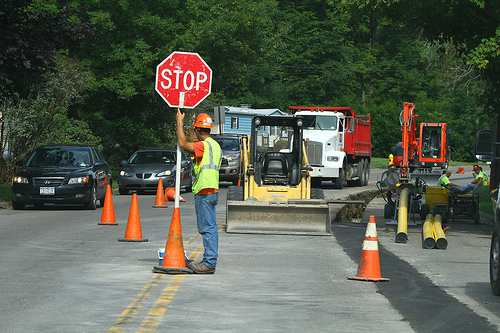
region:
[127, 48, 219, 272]
man holding stop sign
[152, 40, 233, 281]
man holding stop sign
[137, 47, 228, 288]
man holding stop sign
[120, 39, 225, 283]
man holding stop sign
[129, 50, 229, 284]
man holding stop sign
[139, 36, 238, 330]
man holding stop sign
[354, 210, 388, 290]
orange cone in street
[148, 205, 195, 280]
orange cone in street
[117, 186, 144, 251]
orange cone in street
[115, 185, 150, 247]
orange cone in street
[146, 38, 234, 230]
this is an octagon sign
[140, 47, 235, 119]
white writing on the sign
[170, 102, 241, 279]
this is a man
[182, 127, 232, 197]
man wearing a green vest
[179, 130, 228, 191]
man wearing a orange shirt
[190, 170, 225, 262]
man wearing blue jeans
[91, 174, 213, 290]
set of orange cones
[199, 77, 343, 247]
this is a bulldozer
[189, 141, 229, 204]
man wearing a safety vest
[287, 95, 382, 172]
Red and white dump truck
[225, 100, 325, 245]
bulldozer at the work site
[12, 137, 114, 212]
black car on the road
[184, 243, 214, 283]
man wearing brown work boots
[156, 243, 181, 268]
blue water cooler on the ground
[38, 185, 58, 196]
license plate on a car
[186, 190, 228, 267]
man wearing blue jeans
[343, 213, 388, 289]
safety cone on the street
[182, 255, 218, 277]
Man wearing shoes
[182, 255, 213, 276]
Man is wearing brown shoes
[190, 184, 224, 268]
Man is wearing pants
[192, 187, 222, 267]
Man wearing blue pants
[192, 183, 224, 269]
Man is wearing blue pants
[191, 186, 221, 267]
Man wearing blue jeans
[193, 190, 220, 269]
Man is wearing blue jeans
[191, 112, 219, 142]
The man is wearing a helmet.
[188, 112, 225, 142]
The mans safety helmet is orange.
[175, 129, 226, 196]
The mans safety vest is green.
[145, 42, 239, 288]
The man is directing traffic.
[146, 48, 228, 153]
The man is holding a stop sign.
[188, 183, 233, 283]
The man is wearing jeans.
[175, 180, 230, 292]
The mans pants are blue.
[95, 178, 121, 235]
The traffic cone is orange.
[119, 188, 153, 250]
The traffic cone is orange.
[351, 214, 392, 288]
a tall orange and white cone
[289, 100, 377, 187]
a red and white truck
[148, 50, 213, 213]
a red and white stop sign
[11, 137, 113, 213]
the front of a black car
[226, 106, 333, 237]
a small yellow bulldozer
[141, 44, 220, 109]
red and white stop sign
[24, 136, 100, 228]
black car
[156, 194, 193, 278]
orange colored safety cone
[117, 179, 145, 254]
orange colored safety cone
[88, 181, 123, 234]
orange colored safety cone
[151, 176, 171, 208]
orange colored safety cone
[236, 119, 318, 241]
yellow machine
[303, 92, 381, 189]
red black and white heavy truck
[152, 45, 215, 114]
Stop sign above a road.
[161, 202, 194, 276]
Orange cone on a road.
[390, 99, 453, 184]
Red tractor by the road.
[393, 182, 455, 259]
Pipes on a road.